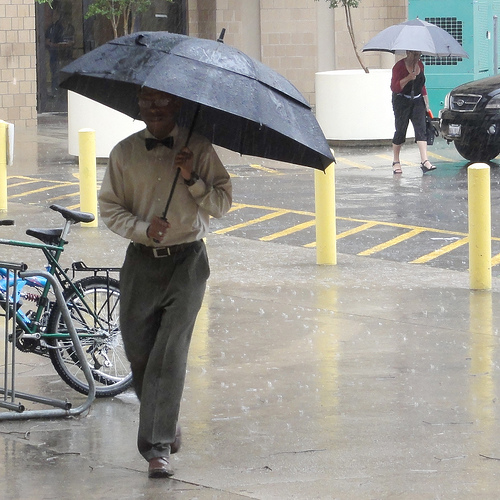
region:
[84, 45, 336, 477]
man walking in rain with umbrella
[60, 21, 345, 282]
man holding large black umbrella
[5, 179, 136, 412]
bikes are behind the man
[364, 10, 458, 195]
woman walking with umbrella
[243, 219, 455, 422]
street is wet with rain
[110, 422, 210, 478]
man wearing brown shoes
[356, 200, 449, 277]
yellow lines on street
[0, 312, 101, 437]
bike rack to park bikes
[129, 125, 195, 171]
man wearing bow tie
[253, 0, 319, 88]
beige brick building in background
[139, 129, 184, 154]
Black bow tie.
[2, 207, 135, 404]
Bicycles parked in a stand.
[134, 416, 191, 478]
Brown leather dress shoes.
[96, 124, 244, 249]
Brown long sleeved shirt.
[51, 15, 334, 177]
A black umbrella.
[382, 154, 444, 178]
Black wedge sandals with straps.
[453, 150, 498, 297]
Cement pole painted yellow.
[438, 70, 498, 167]
Black vehicle with a white license plate.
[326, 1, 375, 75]
Small tree in a huge white planter.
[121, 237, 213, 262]
Black belt with a silver buckle.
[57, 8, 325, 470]
man walking in the rain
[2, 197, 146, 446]
two bikes secured to bike rack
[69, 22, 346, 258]
man carrying black umbrella in the rain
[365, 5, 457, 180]
lady walking in the rain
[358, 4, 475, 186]
lady carrying a black umbrella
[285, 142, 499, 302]
yellow cement divider poles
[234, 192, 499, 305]
yellow caution lines painted in parking lot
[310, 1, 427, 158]
tree planted in outside planter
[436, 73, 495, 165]
front of black SUV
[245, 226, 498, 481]
rain falling on cement sidewalk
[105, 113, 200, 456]
this is a man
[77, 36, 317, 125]
this is an umbrella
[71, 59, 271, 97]
the umbrella is black in color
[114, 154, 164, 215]
the shirt is green in color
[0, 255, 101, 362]
this is a bike beside the man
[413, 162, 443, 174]
the shoe is black in color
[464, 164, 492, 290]
the pole is yellow in color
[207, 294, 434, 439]
the floor is wet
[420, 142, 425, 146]
the woman is light skinned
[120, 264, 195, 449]
the trousers is black in color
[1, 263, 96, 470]
The metal bicycle rack.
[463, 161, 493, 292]
A yellow pole in the area.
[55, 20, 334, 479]
A man with a big black umbrella.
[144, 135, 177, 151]
A little black bow tie.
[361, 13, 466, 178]
A woman with multicolored umbrella.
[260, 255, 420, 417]
Drops of rain on the pavement.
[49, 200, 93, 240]
A raised bicycle seat.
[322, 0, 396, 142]
A container for a tree.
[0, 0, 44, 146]
The tan brick building.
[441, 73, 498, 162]
The bumper of a vehicle.